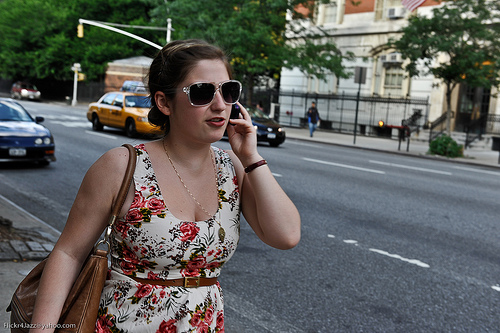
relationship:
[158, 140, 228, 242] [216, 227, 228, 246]
necklace with pendant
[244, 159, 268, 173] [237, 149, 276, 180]
watchband on wrist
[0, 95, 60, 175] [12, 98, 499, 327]
automobile driving on street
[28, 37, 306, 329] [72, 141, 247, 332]
woman has on a dress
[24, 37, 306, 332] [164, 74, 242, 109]
woman wearing sunglasses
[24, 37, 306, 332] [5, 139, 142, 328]
woman has purse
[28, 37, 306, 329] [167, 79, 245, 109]
woman wearing sunglasses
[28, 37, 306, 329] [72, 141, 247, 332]
woman wearing dress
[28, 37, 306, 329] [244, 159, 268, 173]
woman wearing watchband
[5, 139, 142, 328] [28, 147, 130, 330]
purse under arm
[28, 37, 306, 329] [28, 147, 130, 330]
woman has arm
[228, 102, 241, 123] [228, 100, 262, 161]
cell phone in hand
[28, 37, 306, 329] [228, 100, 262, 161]
woman has hand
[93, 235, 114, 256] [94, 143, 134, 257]
loop on strap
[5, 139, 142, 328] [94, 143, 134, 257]
purse has strap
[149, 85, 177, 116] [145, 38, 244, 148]
ear on head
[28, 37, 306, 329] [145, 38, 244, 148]
woman has head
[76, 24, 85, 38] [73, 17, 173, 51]
light hanging on pole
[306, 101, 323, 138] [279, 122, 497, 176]
person walking on sidewalk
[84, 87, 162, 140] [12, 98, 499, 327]
cab on street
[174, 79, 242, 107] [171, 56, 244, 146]
sunglasses are on girl's face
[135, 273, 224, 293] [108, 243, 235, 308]
belt on girl's waist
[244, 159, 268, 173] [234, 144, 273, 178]
watchband on girl's wrist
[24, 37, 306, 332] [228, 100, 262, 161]
woman has hand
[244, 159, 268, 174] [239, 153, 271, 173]
watch on girl's wrist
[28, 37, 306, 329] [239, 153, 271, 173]
woman has girl's wrist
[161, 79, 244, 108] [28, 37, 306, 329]
sunglasses worn by woman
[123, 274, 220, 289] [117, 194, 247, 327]
belt on dress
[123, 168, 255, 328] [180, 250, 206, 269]
dress with flowers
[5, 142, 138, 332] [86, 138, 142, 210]
purse hanging on shoulder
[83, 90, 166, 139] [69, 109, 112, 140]
cab on street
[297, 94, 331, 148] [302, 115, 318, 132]
person with pants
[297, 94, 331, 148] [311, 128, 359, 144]
person walking on sidewalk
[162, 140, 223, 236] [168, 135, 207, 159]
necklace around neck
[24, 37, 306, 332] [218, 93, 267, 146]
woman talking on cellphone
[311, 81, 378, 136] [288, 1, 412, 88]
fence in front of building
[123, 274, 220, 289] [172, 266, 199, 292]
belt with buckle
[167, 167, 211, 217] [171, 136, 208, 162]
chain around neck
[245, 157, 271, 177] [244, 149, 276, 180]
watchband around wrist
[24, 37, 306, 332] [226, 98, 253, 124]
woman talking on cellphone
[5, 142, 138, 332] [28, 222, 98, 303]
purse under arm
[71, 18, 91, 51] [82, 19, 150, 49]
signal attached to arm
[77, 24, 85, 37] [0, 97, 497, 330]
signal suspended above street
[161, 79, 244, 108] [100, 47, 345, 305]
sunglasses on woman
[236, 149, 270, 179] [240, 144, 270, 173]
watch on wrist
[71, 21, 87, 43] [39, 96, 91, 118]
light over street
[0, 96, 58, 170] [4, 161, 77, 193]
automobile on street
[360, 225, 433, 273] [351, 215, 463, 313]
line on street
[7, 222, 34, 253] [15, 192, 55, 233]
bricks on ground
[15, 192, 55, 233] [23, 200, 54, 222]
ground of sidewalk